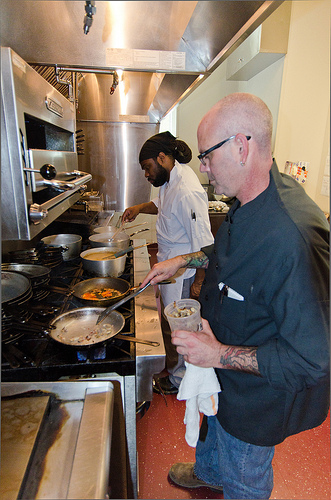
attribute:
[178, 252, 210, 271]
tattoo — blue, red, colorful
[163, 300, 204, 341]
container — white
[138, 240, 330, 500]
floor — pink, part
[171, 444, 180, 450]
spot — white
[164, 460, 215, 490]
shoe — brown, leather, edge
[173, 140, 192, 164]
bun — black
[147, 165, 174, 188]
beard — full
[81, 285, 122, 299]
vegetables — being cooked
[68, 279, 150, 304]
skillet — silver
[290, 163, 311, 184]
dish cloth — white, orange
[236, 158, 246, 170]
earring — silver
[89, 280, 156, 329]
spatula — silver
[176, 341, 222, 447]
towel — white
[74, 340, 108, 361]
flames — blue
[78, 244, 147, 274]
pot — large, silver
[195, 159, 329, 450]
shirt — part, baggy, navy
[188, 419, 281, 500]
jeans — part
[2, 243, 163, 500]
oven — part, edge, black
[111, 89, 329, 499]
man — cooking, mixing food, stirring the pot, a chef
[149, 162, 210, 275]
shirt — white